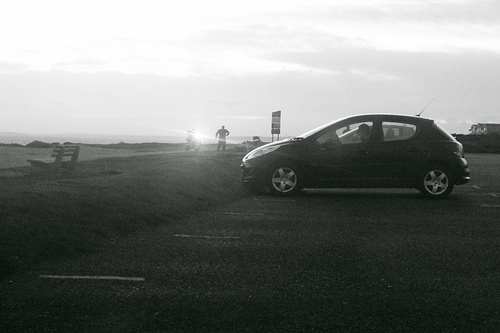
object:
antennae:
[413, 97, 435, 118]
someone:
[357, 124, 371, 143]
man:
[216, 126, 230, 152]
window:
[336, 122, 374, 145]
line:
[38, 275, 145, 282]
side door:
[309, 116, 380, 188]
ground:
[6, 142, 497, 331]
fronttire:
[232, 109, 470, 201]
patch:
[408, 236, 445, 273]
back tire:
[416, 163, 454, 200]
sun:
[194, 132, 204, 138]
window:
[382, 121, 417, 141]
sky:
[2, 3, 499, 119]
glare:
[185, 128, 202, 151]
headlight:
[248, 145, 282, 160]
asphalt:
[0, 152, 499, 331]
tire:
[267, 163, 304, 196]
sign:
[271, 110, 281, 142]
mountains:
[1, 140, 80, 149]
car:
[240, 98, 471, 200]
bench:
[28, 144, 81, 172]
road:
[192, 219, 401, 301]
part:
[100, 71, 163, 117]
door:
[374, 135, 435, 196]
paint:
[172, 235, 240, 239]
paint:
[224, 212, 264, 216]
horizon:
[110, 140, 273, 144]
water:
[1, 131, 295, 141]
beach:
[3, 140, 266, 174]